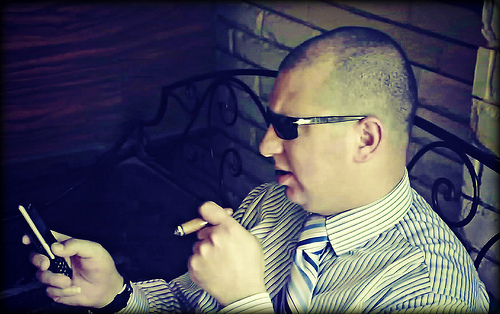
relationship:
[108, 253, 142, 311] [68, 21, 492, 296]
watch on man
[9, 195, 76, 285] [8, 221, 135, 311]
cellphone in hand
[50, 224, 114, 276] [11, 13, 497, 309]
thumb on man